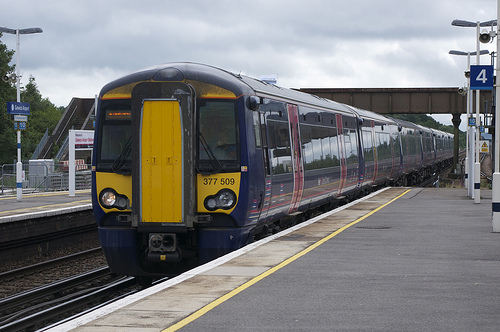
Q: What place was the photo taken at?
A: It was taken at the train station.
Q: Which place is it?
A: It is a train station.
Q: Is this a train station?
A: Yes, it is a train station.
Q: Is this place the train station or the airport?
A: It is the train station.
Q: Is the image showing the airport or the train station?
A: It is showing the train station.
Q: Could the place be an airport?
A: No, it is a train station.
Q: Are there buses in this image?
A: No, there are no buses.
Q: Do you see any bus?
A: No, there are no buses.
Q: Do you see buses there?
A: No, there are no buses.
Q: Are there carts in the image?
A: No, there are no carts.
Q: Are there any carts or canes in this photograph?
A: No, there are no carts or canes.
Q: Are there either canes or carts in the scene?
A: No, there are no carts or canes.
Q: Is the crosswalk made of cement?
A: Yes, the crosswalk is made of cement.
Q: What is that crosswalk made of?
A: The crosswalk is made of cement.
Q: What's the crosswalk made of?
A: The crosswalk is made of concrete.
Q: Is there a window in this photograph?
A: Yes, there is a window.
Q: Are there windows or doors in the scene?
A: Yes, there is a window.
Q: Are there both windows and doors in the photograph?
A: Yes, there are both a window and a door.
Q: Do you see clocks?
A: No, there are no clocks.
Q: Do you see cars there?
A: No, there are no cars.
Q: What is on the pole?
A: The sign is on the pole.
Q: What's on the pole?
A: The sign is on the pole.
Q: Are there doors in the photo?
A: Yes, there is a door.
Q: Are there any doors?
A: Yes, there is a door.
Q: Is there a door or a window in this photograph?
A: Yes, there is a door.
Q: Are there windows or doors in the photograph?
A: Yes, there is a door.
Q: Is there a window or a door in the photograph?
A: Yes, there is a door.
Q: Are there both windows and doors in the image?
A: Yes, there are both a door and a window.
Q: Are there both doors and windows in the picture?
A: Yes, there are both a door and a window.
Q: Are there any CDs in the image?
A: No, there are no cds.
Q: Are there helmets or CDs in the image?
A: No, there are no CDs or helmets.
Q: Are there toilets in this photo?
A: No, there are no toilets.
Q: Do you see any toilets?
A: No, there are no toilets.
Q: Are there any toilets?
A: No, there are no toilets.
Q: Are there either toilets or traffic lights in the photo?
A: No, there are no toilets or traffic lights.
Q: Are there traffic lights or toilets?
A: No, there are no toilets or traffic lights.